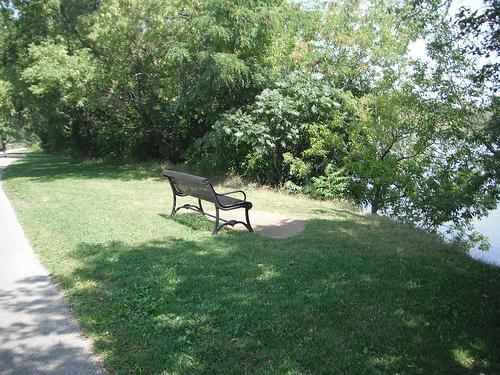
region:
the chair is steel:
[224, 173, 231, 232]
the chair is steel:
[180, 171, 204, 223]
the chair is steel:
[211, 188, 227, 215]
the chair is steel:
[189, 185, 215, 214]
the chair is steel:
[222, 193, 236, 216]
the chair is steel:
[200, 186, 216, 211]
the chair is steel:
[205, 189, 219, 200]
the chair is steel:
[196, 176, 230, 219]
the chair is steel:
[192, 187, 222, 227]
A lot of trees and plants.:
[32, 5, 339, 133]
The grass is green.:
[157, 256, 407, 368]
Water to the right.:
[397, 170, 493, 266]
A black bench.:
[147, 162, 261, 245]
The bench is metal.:
[135, 159, 263, 247]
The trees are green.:
[64, 8, 334, 138]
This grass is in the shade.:
[137, 260, 444, 365]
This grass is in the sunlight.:
[29, 192, 128, 226]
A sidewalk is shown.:
[8, 220, 103, 370]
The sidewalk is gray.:
[2, 235, 92, 370]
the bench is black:
[136, 149, 341, 281]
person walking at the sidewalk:
[0, 125, 22, 167]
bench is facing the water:
[118, 90, 485, 279]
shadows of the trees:
[66, 194, 336, 366]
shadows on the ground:
[116, 165, 336, 366]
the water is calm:
[390, 175, 491, 273]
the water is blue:
[444, 207, 499, 264]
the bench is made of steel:
[143, 110, 328, 302]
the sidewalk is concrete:
[0, 225, 80, 351]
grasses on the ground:
[85, 195, 227, 350]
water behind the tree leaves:
[415, 129, 499, 274]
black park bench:
[156, 167, 263, 257]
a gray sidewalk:
[0, 208, 79, 373]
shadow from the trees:
[45, 232, 225, 373]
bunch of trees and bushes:
[55, 92, 363, 178]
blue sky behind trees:
[0, 1, 497, 45]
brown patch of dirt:
[197, 205, 314, 252]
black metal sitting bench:
[163, 167, 263, 244]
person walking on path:
[0, 121, 12, 163]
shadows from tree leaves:
[0, 272, 63, 372]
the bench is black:
[125, 133, 273, 327]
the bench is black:
[86, 108, 388, 373]